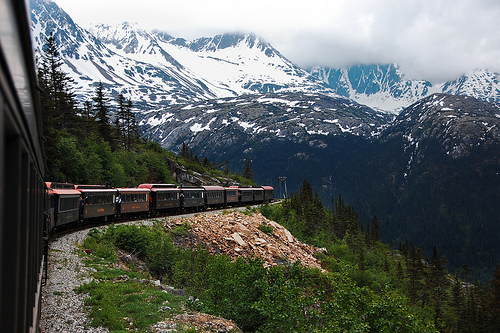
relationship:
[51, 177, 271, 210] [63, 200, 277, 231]
train on track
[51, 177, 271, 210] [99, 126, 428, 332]
train around mountain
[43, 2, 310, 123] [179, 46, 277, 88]
mountain has snow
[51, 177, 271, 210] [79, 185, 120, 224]
train has car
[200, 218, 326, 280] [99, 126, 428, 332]
rocks on hill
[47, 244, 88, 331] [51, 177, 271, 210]
gravels under train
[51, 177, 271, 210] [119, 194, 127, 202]
train has window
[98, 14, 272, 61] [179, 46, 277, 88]
peaks covered in snow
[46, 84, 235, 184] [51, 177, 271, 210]
forest behind train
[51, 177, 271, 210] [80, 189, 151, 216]
train has cars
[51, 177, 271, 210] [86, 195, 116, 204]
train has windows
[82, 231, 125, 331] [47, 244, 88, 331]
plants in gravel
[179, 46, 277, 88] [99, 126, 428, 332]
snow on top of mountain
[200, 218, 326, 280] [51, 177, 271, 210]
rocks beside train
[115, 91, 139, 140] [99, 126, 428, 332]
trees on mountain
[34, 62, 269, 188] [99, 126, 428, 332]
trees on top of mountain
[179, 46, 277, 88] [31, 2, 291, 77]
snow on top of mountains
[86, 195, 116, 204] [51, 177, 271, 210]
windows on train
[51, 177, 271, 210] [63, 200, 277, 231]
train on tracks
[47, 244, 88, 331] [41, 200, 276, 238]
gravel beside track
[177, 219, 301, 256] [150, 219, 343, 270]
woodchips beside ground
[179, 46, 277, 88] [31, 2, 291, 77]
snow on mountains